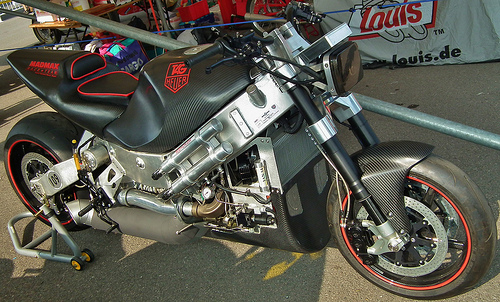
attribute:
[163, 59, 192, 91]
emblem — red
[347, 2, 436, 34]
sign — white, red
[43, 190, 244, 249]
pipe — silver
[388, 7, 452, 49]
object — red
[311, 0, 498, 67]
banner — crinkled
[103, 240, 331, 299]
shadows — dark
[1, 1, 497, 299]
bike — red, black, silver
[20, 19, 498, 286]
motorcycle — one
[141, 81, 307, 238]
engine — silver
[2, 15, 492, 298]
motorcycle — black, parked, silver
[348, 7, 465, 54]
sign — big, white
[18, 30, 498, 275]
motorbike — black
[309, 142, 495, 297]
wheels — little, yellow, black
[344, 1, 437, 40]
logo — white, red, black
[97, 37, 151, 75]
bag — purple, pink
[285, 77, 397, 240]
spoke — black, silver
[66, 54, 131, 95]
seat — black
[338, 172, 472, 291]
stripe — narrow, red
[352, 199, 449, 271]
rim — red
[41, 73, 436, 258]
motorcycle — grey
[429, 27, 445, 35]
symbol — small, black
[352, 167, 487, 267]
tire — red, white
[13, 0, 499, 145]
pole — silver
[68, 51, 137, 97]
trim — red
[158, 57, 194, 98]
design — red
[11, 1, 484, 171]
pole — silver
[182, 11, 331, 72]
handles — black